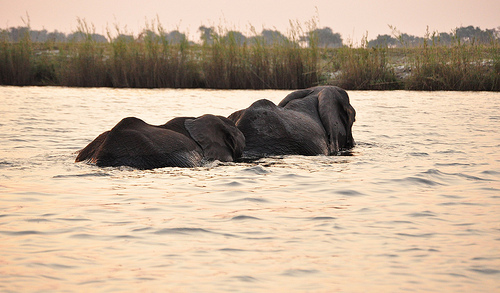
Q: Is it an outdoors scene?
A: Yes, it is outdoors.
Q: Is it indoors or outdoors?
A: It is outdoors.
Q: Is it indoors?
A: No, it is outdoors.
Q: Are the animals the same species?
A: Yes, all the animals are elephants.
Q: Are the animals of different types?
A: No, all the animals are elephants.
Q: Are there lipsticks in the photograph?
A: No, there are no lipsticks.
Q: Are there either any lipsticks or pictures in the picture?
A: No, there are no lipsticks or pictures.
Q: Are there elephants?
A: Yes, there is an elephant.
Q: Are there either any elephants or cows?
A: Yes, there is an elephant.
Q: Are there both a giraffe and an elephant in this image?
A: No, there is an elephant but no giraffes.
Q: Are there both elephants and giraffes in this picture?
A: No, there is an elephant but no giraffes.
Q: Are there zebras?
A: No, there are no zebras.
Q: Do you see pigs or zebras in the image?
A: No, there are no zebras or pigs.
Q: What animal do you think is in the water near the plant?
A: The elephant is in the water.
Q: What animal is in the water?
A: The elephant is in the water.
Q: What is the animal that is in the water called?
A: The animal is an elephant.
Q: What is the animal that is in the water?
A: The animal is an elephant.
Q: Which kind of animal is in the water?
A: The animal is an elephant.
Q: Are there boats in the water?
A: No, there is an elephant in the water.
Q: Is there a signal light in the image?
A: No, there are no traffic lights.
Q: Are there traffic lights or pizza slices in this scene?
A: No, there are no traffic lights or pizza slices.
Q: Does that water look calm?
A: Yes, the water is calm.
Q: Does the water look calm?
A: Yes, the water is calm.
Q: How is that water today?
A: The water is calm.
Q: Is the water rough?
A: No, the water is calm.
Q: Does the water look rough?
A: No, the water is calm.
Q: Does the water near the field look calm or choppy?
A: The water is calm.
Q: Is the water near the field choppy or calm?
A: The water is calm.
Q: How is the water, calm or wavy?
A: The water is calm.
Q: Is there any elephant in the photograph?
A: Yes, there is an elephant.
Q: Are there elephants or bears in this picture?
A: Yes, there is an elephant.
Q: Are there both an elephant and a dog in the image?
A: No, there is an elephant but no dogs.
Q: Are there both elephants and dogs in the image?
A: No, there is an elephant but no dogs.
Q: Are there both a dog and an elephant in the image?
A: No, there is an elephant but no dogs.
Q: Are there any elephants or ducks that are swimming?
A: Yes, the elephant is swimming.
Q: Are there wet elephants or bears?
A: Yes, there is a wet elephant.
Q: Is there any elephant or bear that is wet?
A: Yes, the elephant is wet.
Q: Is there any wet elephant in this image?
A: Yes, there is a wet elephant.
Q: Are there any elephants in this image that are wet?
A: Yes, there is an elephant that is wet.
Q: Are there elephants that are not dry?
A: Yes, there is a wet elephant.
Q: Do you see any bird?
A: No, there are no birds.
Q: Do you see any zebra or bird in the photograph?
A: No, there are no birds or zebras.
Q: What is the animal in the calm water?
A: The animal is an elephant.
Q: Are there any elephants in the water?
A: Yes, there is an elephant in the water.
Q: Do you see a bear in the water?
A: No, there is an elephant in the water.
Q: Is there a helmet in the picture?
A: No, there are no helmets.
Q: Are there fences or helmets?
A: No, there are no helmets or fences.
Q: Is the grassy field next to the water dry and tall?
A: Yes, the field is dry and tall.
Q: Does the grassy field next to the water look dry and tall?
A: Yes, the field is dry and tall.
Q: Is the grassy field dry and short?
A: No, the field is dry but tall.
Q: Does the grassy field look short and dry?
A: No, the field is dry but tall.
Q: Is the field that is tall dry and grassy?
A: Yes, the field is dry and grassy.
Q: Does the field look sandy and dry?
A: No, the field is dry but grassy.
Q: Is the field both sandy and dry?
A: No, the field is dry but grassy.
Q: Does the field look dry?
A: Yes, the field is dry.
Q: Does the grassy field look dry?
A: Yes, the field is dry.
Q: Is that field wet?
A: No, the field is dry.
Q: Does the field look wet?
A: No, the field is dry.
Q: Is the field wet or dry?
A: The field is dry.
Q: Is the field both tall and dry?
A: Yes, the field is tall and dry.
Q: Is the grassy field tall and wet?
A: No, the field is tall but dry.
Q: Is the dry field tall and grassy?
A: Yes, the field is tall and grassy.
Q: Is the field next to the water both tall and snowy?
A: No, the field is tall but grassy.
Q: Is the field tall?
A: Yes, the field is tall.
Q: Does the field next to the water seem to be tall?
A: Yes, the field is tall.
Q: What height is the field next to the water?
A: The field is tall.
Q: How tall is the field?
A: The field is tall.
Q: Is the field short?
A: No, the field is tall.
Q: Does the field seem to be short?
A: No, the field is tall.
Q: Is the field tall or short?
A: The field is tall.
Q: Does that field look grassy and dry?
A: Yes, the field is grassy and dry.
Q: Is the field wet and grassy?
A: No, the field is grassy but dry.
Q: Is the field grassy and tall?
A: Yes, the field is grassy and tall.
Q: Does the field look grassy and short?
A: No, the field is grassy but tall.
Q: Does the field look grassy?
A: Yes, the field is grassy.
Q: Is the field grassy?
A: Yes, the field is grassy.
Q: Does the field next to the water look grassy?
A: Yes, the field is grassy.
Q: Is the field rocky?
A: No, the field is grassy.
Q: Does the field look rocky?
A: No, the field is grassy.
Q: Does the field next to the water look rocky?
A: No, the field is grassy.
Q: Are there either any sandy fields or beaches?
A: No, there is a field but it is grassy.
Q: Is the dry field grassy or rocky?
A: The field is grassy.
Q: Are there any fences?
A: No, there are no fences.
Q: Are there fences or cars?
A: No, there are no fences or cars.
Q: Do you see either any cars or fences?
A: No, there are no fences or cars.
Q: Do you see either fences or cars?
A: No, there are no fences or cars.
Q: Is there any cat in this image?
A: No, there are no cats.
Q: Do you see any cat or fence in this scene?
A: No, there are no cats or fences.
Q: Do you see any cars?
A: No, there are no cars.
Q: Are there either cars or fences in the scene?
A: No, there are no cars or fences.